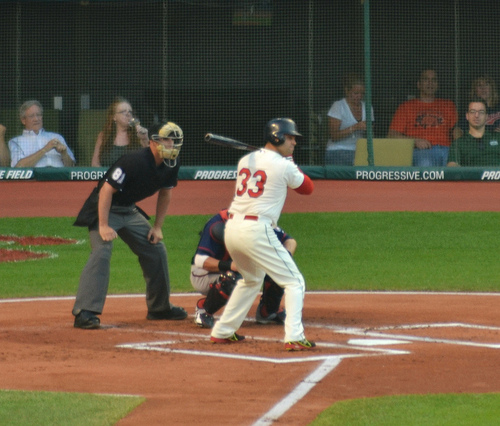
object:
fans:
[0, 65, 499, 164]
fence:
[1, 1, 498, 177]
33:
[236, 168, 267, 199]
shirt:
[227, 145, 304, 221]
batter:
[210, 118, 319, 353]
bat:
[202, 130, 264, 153]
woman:
[323, 74, 376, 165]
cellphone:
[365, 118, 376, 130]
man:
[9, 99, 77, 169]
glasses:
[23, 112, 44, 119]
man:
[444, 96, 497, 168]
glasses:
[468, 109, 487, 115]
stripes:
[2, 287, 497, 426]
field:
[0, 182, 499, 426]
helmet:
[263, 116, 303, 146]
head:
[266, 117, 301, 157]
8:
[112, 168, 122, 181]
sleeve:
[105, 155, 138, 191]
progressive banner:
[0, 165, 500, 185]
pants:
[210, 215, 307, 342]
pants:
[71, 206, 172, 316]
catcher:
[188, 207, 298, 329]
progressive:
[192, 166, 238, 180]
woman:
[90, 94, 150, 171]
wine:
[128, 117, 141, 128]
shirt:
[96, 147, 179, 208]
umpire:
[71, 120, 187, 328]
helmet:
[148, 116, 183, 168]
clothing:
[73, 147, 177, 316]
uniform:
[208, 148, 314, 342]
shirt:
[7, 125, 76, 167]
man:
[386, 69, 458, 167]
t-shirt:
[389, 96, 457, 146]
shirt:
[446, 127, 499, 169]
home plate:
[349, 335, 411, 348]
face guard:
[151, 129, 185, 168]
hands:
[46, 138, 67, 155]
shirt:
[323, 96, 376, 152]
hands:
[99, 226, 164, 244]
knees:
[92, 238, 168, 255]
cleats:
[208, 332, 317, 354]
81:
[112, 168, 126, 184]